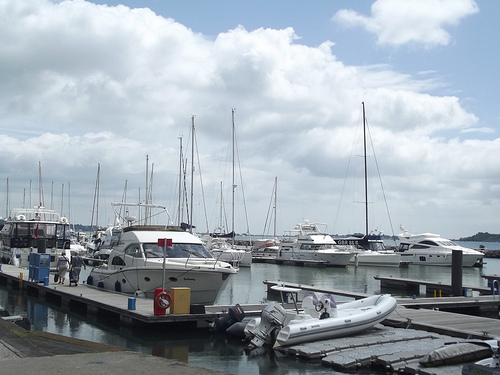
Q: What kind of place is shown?
A: It is a harbor.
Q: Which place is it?
A: It is a harbor.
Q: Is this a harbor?
A: Yes, it is a harbor.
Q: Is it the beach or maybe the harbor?
A: It is the harbor.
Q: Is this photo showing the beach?
A: No, the picture is showing the harbor.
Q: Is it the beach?
A: No, it is the harbor.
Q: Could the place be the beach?
A: No, it is the harbor.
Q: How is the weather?
A: It is cloudy.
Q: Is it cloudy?
A: Yes, it is cloudy.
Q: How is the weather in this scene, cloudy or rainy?
A: It is cloudy.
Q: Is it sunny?
A: No, it is cloudy.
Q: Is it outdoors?
A: Yes, it is outdoors.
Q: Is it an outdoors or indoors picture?
A: It is outdoors.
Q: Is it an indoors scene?
A: No, it is outdoors.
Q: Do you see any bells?
A: No, there are no bells.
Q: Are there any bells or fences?
A: No, there are no bells or fences.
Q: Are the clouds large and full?
A: Yes, the clouds are large and full.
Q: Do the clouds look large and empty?
A: No, the clouds are large but full.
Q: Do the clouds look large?
A: Yes, the clouds are large.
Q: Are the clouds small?
A: No, the clouds are large.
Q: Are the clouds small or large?
A: The clouds are large.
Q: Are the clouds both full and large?
A: Yes, the clouds are full and large.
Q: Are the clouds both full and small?
A: No, the clouds are full but large.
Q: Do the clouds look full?
A: Yes, the clouds are full.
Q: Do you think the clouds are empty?
A: No, the clouds are full.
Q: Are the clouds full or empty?
A: The clouds are full.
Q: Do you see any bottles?
A: No, there are no bottles.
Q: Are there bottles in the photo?
A: No, there are no bottles.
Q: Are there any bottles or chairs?
A: No, there are no bottles or chairs.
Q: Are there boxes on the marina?
A: Yes, there is a box on the marina.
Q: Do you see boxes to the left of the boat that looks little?
A: Yes, there is a box to the left of the boat.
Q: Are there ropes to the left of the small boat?
A: No, there is a box to the left of the boat.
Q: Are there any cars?
A: No, there are no cars.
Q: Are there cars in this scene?
A: No, there are no cars.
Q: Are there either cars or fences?
A: No, there are no cars or fences.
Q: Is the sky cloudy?
A: Yes, the sky is cloudy.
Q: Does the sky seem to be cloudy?
A: Yes, the sky is cloudy.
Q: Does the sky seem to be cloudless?
A: No, the sky is cloudy.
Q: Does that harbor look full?
A: Yes, the harbor is full.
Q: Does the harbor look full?
A: Yes, the harbor is full.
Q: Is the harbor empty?
A: No, the harbor is full.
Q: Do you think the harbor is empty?
A: No, the harbor is full.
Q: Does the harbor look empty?
A: No, the harbor is full.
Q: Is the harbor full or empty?
A: The harbor is full.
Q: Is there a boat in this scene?
A: Yes, there is a boat.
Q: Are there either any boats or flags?
A: Yes, there is a boat.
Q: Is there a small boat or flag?
A: Yes, there is a small boat.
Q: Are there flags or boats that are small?
A: Yes, the boat is small.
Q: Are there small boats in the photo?
A: Yes, there is a small boat.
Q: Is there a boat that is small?
A: Yes, there is a boat that is small.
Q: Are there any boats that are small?
A: Yes, there is a boat that is small.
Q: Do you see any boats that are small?
A: Yes, there is a boat that is small.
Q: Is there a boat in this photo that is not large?
A: Yes, there is a small boat.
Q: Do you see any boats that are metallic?
A: Yes, there is a metal boat.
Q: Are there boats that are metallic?
A: Yes, there is a boat that is metallic.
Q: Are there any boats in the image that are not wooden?
A: Yes, there is a metallic boat.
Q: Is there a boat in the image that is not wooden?
A: Yes, there is a metallic boat.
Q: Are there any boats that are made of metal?
A: Yes, there is a boat that is made of metal.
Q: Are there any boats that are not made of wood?
A: Yes, there is a boat that is made of metal.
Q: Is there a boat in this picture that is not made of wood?
A: Yes, there is a boat that is made of metal.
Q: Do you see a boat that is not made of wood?
A: Yes, there is a boat that is made of metal.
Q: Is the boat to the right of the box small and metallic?
A: Yes, the boat is small and metallic.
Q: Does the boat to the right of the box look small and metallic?
A: Yes, the boat is small and metallic.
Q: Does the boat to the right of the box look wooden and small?
A: No, the boat is small but metallic.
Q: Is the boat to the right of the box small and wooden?
A: No, the boat is small but metallic.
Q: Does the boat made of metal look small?
A: Yes, the boat is small.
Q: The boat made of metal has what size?
A: The boat is small.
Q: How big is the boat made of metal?
A: The boat is small.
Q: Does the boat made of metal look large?
A: No, the boat is small.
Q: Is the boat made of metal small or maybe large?
A: The boat is small.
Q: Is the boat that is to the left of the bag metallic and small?
A: Yes, the boat is metallic and small.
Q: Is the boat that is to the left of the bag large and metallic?
A: No, the boat is metallic but small.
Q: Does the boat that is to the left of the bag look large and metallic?
A: No, the boat is metallic but small.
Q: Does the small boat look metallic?
A: Yes, the boat is metallic.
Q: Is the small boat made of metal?
A: Yes, the boat is made of metal.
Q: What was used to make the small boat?
A: The boat is made of metal.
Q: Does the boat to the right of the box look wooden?
A: No, the boat is metallic.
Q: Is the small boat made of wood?
A: No, the boat is made of metal.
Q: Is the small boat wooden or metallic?
A: The boat is metallic.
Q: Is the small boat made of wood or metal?
A: The boat is made of metal.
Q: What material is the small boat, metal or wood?
A: The boat is made of metal.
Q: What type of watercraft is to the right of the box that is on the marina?
A: The watercraft is a boat.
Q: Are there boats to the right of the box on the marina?
A: Yes, there is a boat to the right of the box.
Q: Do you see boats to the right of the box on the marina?
A: Yes, there is a boat to the right of the box.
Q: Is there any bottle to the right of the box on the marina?
A: No, there is a boat to the right of the box.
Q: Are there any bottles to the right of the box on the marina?
A: No, there is a boat to the right of the box.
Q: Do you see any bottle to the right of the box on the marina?
A: No, there is a boat to the right of the box.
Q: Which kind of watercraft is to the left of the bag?
A: The watercraft is a boat.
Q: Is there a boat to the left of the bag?
A: Yes, there is a boat to the left of the bag.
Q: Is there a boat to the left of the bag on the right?
A: Yes, there is a boat to the left of the bag.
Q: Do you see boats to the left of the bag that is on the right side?
A: Yes, there is a boat to the left of the bag.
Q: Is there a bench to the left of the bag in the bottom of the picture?
A: No, there is a boat to the left of the bag.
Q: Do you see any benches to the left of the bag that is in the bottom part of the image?
A: No, there is a boat to the left of the bag.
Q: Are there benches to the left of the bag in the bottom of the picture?
A: No, there is a boat to the left of the bag.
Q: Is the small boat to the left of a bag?
A: Yes, the boat is to the left of a bag.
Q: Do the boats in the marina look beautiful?
A: Yes, the boats are beautiful.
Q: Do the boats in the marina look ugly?
A: No, the boats are beautiful.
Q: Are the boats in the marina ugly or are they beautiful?
A: The boats are beautiful.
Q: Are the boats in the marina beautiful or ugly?
A: The boats are beautiful.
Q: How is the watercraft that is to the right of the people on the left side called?
A: The watercraft is boats.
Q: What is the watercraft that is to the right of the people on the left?
A: The watercraft is boats.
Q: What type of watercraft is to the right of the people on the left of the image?
A: The watercraft is boats.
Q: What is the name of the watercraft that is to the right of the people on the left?
A: The watercraft is boats.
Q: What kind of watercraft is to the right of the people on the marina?
A: The watercraft is boats.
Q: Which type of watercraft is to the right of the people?
A: The watercraft is boats.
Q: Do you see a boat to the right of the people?
A: Yes, there are boats to the right of the people.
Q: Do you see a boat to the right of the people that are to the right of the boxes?
A: Yes, there are boats to the right of the people.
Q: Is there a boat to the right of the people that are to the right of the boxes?
A: Yes, there are boats to the right of the people.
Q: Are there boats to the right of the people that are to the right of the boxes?
A: Yes, there are boats to the right of the people.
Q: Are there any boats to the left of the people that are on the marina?
A: No, the boats are to the right of the people.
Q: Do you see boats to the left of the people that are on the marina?
A: No, the boats are to the right of the people.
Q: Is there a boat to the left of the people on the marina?
A: No, the boats are to the right of the people.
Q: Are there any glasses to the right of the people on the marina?
A: No, there are boats to the right of the people.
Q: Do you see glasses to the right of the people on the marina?
A: No, there are boats to the right of the people.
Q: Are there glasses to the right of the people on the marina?
A: No, there are boats to the right of the people.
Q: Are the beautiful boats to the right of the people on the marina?
A: Yes, the boats are to the right of the people.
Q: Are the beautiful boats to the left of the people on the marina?
A: No, the boats are to the right of the people.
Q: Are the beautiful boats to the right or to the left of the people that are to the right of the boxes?
A: The boats are to the right of the people.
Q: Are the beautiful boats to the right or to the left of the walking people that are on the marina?
A: The boats are to the right of the people.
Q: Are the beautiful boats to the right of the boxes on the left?
A: Yes, the boats are to the right of the boxes.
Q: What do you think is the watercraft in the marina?
A: The watercraft is boats.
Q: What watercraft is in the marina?
A: The watercraft is boats.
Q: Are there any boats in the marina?
A: Yes, there are boats in the marina.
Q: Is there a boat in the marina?
A: Yes, there are boats in the marina.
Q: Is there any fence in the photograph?
A: No, there are no fences.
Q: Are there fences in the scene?
A: No, there are no fences.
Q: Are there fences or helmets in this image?
A: No, there are no fences or helmets.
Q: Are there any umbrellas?
A: No, there are no umbrellas.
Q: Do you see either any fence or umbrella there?
A: No, there are no umbrellas or fences.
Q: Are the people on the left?
A: Yes, the people are on the left of the image.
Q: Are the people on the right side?
A: No, the people are on the left of the image.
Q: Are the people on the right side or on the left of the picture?
A: The people are on the left of the image.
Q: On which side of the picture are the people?
A: The people are on the left of the image.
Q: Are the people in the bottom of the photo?
A: Yes, the people are in the bottom of the image.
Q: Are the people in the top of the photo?
A: No, the people are in the bottom of the image.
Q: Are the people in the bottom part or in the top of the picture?
A: The people are in the bottom of the image.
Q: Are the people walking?
A: Yes, the people are walking.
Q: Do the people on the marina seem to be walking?
A: Yes, the people are walking.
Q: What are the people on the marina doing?
A: The people are walking.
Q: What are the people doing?
A: The people are walking.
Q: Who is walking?
A: The people are walking.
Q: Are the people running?
A: No, the people are walking.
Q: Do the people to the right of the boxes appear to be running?
A: No, the people are walking.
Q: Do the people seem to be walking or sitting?
A: The people are walking.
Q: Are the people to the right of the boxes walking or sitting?
A: The people are walking.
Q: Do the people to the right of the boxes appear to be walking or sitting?
A: The people are walking.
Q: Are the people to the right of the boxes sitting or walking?
A: The people are walking.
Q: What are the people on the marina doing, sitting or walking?
A: The people are walking.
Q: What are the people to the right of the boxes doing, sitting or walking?
A: The people are walking.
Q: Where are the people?
A: The people are on the marina.